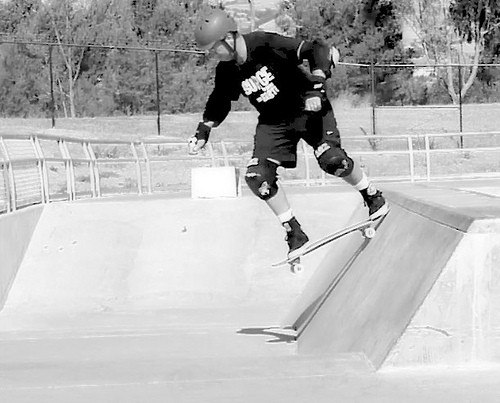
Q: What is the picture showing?
A: It is showing a skate park.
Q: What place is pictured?
A: It is a skate park.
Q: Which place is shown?
A: It is a skate park.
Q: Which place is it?
A: It is a skate park.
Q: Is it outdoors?
A: Yes, it is outdoors.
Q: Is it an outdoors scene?
A: Yes, it is outdoors.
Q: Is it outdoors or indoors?
A: It is outdoors.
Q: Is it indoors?
A: No, it is outdoors.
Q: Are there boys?
A: No, there are no boys.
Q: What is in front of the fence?
A: The skate park is in front of the fence.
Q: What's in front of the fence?
A: The skate park is in front of the fence.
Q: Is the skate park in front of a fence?
A: Yes, the skate park is in front of a fence.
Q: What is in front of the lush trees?
A: The skate park is in front of the trees.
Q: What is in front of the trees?
A: The skate park is in front of the trees.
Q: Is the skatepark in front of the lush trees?
A: Yes, the skatepark is in front of the trees.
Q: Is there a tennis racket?
A: No, there are no rackets.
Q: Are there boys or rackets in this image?
A: No, there are no rackets or boys.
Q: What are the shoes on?
A: The shoes are on the skateboard.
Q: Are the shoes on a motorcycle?
A: No, the shoes are on the skateboard.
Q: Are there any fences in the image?
A: Yes, there is a fence.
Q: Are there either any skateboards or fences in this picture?
A: Yes, there is a fence.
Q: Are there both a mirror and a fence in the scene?
A: No, there is a fence but no mirrors.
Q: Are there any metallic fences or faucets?
A: Yes, there is a metal fence.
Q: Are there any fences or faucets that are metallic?
A: Yes, the fence is metallic.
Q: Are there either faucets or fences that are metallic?
A: Yes, the fence is metallic.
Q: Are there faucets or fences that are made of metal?
A: Yes, the fence is made of metal.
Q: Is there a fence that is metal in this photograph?
A: Yes, there is a metal fence.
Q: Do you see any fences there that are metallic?
A: Yes, there is a fence that is metallic.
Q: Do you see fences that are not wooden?
A: Yes, there is a metallic fence.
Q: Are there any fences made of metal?
A: Yes, there is a fence that is made of metal.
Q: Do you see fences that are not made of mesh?
A: Yes, there is a fence that is made of metal.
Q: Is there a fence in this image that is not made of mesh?
A: Yes, there is a fence that is made of metal.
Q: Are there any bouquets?
A: No, there are no bouquets.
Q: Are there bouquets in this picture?
A: No, there are no bouquets.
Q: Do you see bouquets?
A: No, there are no bouquets.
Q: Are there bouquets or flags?
A: No, there are no bouquets or flags.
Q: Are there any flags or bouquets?
A: No, there are no bouquets or flags.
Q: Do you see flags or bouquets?
A: No, there are no bouquets or flags.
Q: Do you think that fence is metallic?
A: Yes, the fence is metallic.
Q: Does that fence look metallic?
A: Yes, the fence is metallic.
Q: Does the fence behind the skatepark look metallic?
A: Yes, the fence is metallic.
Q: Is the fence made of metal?
A: Yes, the fence is made of metal.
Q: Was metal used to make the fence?
A: Yes, the fence is made of metal.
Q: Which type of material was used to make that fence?
A: The fence is made of metal.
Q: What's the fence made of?
A: The fence is made of metal.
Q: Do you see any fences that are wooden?
A: No, there is a fence but it is metallic.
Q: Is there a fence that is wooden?
A: No, there is a fence but it is metallic.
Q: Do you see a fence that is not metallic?
A: No, there is a fence but it is metallic.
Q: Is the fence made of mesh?
A: No, the fence is made of metal.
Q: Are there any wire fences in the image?
A: No, there is a fence but it is made of metal.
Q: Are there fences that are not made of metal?
A: No, there is a fence but it is made of metal.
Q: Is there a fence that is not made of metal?
A: No, there is a fence but it is made of metal.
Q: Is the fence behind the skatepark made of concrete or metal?
A: The fence is made of metal.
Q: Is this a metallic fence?
A: Yes, this is a metallic fence.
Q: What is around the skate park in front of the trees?
A: The fence is around the skate park.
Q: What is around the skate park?
A: The fence is around the skate park.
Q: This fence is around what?
A: The fence is around the skatepark.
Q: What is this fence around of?
A: The fence is around the skatepark.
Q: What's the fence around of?
A: The fence is around the skatepark.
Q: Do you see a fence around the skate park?
A: Yes, there is a fence around the skate park.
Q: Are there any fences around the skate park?
A: Yes, there is a fence around the skate park.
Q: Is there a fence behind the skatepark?
A: Yes, there is a fence behind the skatepark.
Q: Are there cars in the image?
A: No, there are no cars.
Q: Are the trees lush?
A: Yes, the trees are lush.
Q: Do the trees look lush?
A: Yes, the trees are lush.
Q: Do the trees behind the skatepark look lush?
A: Yes, the trees are lush.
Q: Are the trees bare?
A: No, the trees are lush.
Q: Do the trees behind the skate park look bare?
A: No, the trees are lush.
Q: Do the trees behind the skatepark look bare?
A: No, the trees are lush.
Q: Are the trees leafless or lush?
A: The trees are lush.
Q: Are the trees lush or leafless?
A: The trees are lush.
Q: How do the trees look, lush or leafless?
A: The trees are lush.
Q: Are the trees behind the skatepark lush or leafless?
A: The trees are lush.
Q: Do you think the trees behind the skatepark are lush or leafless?
A: The trees are lush.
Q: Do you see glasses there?
A: No, there are no glasses.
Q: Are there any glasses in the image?
A: No, there are no glasses.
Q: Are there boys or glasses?
A: No, there are no glasses or boys.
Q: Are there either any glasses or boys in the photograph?
A: No, there are no glasses or boys.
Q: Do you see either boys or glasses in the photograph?
A: No, there are no glasses or boys.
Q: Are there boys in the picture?
A: No, there are no boys.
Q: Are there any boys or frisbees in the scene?
A: No, there are no boys or frisbees.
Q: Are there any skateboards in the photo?
A: Yes, there is a skateboard.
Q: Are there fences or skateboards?
A: Yes, there is a skateboard.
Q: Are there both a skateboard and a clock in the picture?
A: No, there is a skateboard but no clocks.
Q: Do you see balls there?
A: No, there are no balls.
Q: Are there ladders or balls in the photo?
A: No, there are no balls or ladders.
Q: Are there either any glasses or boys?
A: No, there are no boys or glasses.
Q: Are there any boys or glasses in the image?
A: No, there are no boys or glasses.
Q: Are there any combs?
A: No, there are no combs.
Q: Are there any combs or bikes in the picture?
A: No, there are no combs or bikes.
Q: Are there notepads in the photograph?
A: No, there are no notepads.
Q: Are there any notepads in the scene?
A: No, there are no notepads.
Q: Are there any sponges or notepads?
A: No, there are no notepads or sponges.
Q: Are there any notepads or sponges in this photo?
A: No, there are no notepads or sponges.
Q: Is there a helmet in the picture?
A: Yes, there is a helmet.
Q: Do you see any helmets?
A: Yes, there is a helmet.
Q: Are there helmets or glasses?
A: Yes, there is a helmet.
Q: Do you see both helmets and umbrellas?
A: No, there is a helmet but no umbrellas.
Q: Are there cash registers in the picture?
A: No, there are no cash registers.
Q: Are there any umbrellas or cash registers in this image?
A: No, there are no cash registers or umbrellas.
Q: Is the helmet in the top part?
A: Yes, the helmet is in the top of the image.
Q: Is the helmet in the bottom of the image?
A: No, the helmet is in the top of the image.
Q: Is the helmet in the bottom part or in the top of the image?
A: The helmet is in the top of the image.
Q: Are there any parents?
A: No, there are no parents.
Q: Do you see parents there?
A: No, there are no parents.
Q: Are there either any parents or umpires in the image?
A: No, there are no parents or umpires.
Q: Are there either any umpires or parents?
A: No, there are no parents or umpires.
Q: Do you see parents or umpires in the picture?
A: No, there are no parents or umpires.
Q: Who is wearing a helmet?
A: The man is wearing a helmet.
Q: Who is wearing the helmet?
A: The man is wearing a helmet.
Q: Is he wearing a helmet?
A: Yes, the man is wearing a helmet.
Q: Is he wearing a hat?
A: No, the man is wearing a helmet.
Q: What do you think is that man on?
A: The man is on the skateboard.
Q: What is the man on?
A: The man is on the skateboard.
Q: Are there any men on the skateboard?
A: Yes, there is a man on the skateboard.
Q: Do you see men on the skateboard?
A: Yes, there is a man on the skateboard.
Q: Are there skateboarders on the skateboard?
A: No, there is a man on the skateboard.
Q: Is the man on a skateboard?
A: Yes, the man is on a skateboard.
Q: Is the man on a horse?
A: No, the man is on a skateboard.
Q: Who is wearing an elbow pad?
A: The man is wearing an elbow pad.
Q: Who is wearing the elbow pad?
A: The man is wearing an elbow pad.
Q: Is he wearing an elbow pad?
A: Yes, the man is wearing an elbow pad.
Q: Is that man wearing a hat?
A: No, the man is wearing an elbow pad.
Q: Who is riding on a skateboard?
A: The man is riding on a skateboard.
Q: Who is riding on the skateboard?
A: The man is riding on a skateboard.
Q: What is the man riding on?
A: The man is riding on a skateboard.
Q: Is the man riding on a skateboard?
A: Yes, the man is riding on a skateboard.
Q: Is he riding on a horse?
A: No, the man is riding on a skateboard.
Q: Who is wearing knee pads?
A: The man is wearing knee pads.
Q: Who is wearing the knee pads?
A: The man is wearing knee pads.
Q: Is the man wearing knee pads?
A: Yes, the man is wearing knee pads.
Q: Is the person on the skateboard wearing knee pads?
A: Yes, the man is wearing knee pads.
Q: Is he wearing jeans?
A: No, the man is wearing knee pads.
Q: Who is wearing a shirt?
A: The man is wearing a shirt.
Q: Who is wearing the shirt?
A: The man is wearing a shirt.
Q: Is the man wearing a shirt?
A: Yes, the man is wearing a shirt.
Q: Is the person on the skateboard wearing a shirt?
A: Yes, the man is wearing a shirt.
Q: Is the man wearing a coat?
A: No, the man is wearing a shirt.